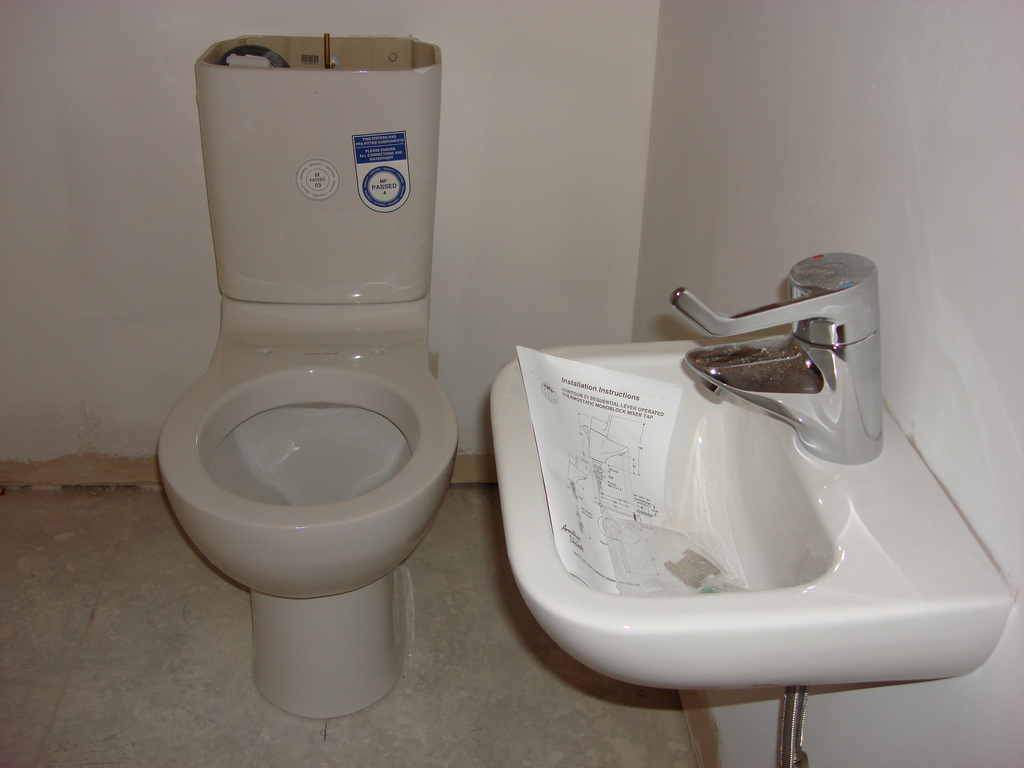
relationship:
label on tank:
[348, 111, 431, 218] [191, 39, 470, 335]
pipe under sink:
[776, 666, 822, 764] [490, 253, 1015, 690]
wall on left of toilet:
[8, 7, 659, 476] [165, 41, 481, 716]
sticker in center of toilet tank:
[282, 145, 349, 208] [187, 7, 468, 319]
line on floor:
[29, 575, 146, 764] [4, 448, 728, 755]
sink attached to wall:
[490, 253, 1015, 690] [631, 5, 1018, 764]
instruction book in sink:
[508, 320, 737, 627] [490, 253, 1015, 690]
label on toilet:
[351, 130, 412, 215] [182, 35, 496, 638]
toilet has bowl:
[165, 41, 481, 716] [169, 342, 429, 563]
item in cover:
[659, 530, 722, 587] [588, 487, 753, 591]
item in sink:
[659, 530, 722, 587] [490, 253, 1015, 690]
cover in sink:
[588, 487, 753, 591] [490, 253, 1015, 690]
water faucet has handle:
[670, 253, 883, 466] [666, 234, 876, 351]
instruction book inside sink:
[517, 344, 686, 596] [480, 245, 1021, 760]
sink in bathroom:
[497, 340, 1018, 710] [9, 5, 1018, 760]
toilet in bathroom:
[158, 33, 460, 719] [9, 5, 1018, 760]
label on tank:
[351, 130, 412, 215] [194, 34, 443, 306]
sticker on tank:
[293, 157, 343, 201] [194, 34, 443, 306]